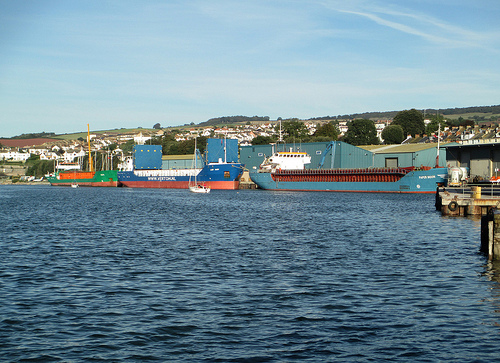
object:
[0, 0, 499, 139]
sky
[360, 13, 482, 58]
clouds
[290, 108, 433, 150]
trees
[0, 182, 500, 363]
water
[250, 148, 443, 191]
boats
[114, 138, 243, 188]
boat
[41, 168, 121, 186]
boat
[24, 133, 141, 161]
houses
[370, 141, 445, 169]
buildings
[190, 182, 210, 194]
boat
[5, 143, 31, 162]
building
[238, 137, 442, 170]
building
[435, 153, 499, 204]
pier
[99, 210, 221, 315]
waves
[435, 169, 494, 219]
dock